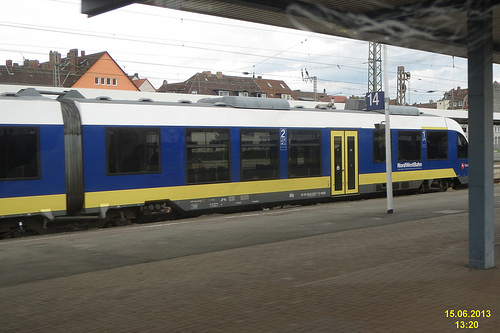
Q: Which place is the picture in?
A: It is at the train station.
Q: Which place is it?
A: It is a train station.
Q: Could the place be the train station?
A: Yes, it is the train station.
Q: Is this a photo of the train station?
A: Yes, it is showing the train station.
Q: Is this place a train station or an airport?
A: It is a train station.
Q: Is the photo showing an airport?
A: No, the picture is showing a train station.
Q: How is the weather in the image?
A: It is cloudy.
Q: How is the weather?
A: It is cloudy.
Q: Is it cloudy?
A: Yes, it is cloudy.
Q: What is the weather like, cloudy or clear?
A: It is cloudy.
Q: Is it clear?
A: No, it is cloudy.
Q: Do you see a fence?
A: No, there are no fences.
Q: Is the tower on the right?
A: Yes, the tower is on the right of the image.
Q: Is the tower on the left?
A: No, the tower is on the right of the image.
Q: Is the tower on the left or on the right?
A: The tower is on the right of the image.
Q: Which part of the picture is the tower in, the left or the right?
A: The tower is on the right of the image.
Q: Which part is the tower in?
A: The tower is on the right of the image.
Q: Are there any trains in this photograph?
A: Yes, there is a train.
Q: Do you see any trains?
A: Yes, there is a train.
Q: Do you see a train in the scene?
A: Yes, there is a train.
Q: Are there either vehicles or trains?
A: Yes, there is a train.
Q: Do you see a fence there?
A: No, there are no fences.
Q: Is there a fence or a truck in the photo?
A: No, there are no fences or trucks.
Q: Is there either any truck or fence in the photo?
A: No, there are no fences or trucks.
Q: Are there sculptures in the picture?
A: No, there are no sculptures.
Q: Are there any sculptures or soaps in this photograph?
A: No, there are no sculptures or soaps.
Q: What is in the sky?
A: The clouds are in the sky.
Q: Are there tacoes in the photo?
A: No, there are no tacoes.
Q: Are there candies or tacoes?
A: No, there are no tacoes or candies.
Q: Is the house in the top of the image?
A: Yes, the house is in the top of the image.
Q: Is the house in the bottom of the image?
A: No, the house is in the top of the image.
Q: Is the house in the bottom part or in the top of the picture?
A: The house is in the top of the image.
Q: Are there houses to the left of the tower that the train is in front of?
A: Yes, there is a house to the left of the tower.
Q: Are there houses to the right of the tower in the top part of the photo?
A: No, the house is to the left of the tower.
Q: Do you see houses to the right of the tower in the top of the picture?
A: No, the house is to the left of the tower.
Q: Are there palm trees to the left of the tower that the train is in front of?
A: No, there is a house to the left of the tower.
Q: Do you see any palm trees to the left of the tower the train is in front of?
A: No, there is a house to the left of the tower.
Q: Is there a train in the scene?
A: Yes, there is a train.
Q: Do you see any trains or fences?
A: Yes, there is a train.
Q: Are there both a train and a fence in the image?
A: No, there is a train but no fences.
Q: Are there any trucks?
A: No, there are no trucks.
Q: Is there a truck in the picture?
A: No, there are no trucks.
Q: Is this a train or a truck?
A: This is a train.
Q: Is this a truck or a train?
A: This is a train.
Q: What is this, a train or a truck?
A: This is a train.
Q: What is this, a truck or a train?
A: This is a train.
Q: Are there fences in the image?
A: No, there are no fences.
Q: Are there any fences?
A: No, there are no fences.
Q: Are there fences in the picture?
A: No, there are no fences.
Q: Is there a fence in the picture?
A: No, there are no fences.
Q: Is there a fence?
A: No, there are no fences.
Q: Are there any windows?
A: Yes, there are windows.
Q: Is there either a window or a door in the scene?
A: Yes, there are windows.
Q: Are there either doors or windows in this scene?
A: Yes, there are windows.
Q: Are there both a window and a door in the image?
A: Yes, there are both a window and a door.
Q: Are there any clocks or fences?
A: No, there are no fences or clocks.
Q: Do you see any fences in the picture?
A: No, there are no fences.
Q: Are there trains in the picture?
A: Yes, there is a train.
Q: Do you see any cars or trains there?
A: Yes, there is a train.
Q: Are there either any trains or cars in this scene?
A: Yes, there is a train.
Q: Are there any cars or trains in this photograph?
A: Yes, there is a train.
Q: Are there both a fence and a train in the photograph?
A: No, there is a train but no fences.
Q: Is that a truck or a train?
A: That is a train.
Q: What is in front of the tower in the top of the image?
A: The train is in front of the tower.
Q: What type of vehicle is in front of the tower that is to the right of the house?
A: The vehicle is a train.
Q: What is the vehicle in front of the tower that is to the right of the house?
A: The vehicle is a train.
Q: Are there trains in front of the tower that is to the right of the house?
A: Yes, there is a train in front of the tower.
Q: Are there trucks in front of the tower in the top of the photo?
A: No, there is a train in front of the tower.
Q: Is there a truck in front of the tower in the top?
A: No, there is a train in front of the tower.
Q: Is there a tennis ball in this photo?
A: No, there are no tennis balls.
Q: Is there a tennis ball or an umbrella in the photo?
A: No, there are no tennis balls or umbrellas.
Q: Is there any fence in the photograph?
A: No, there are no fences.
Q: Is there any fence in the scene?
A: No, there are no fences.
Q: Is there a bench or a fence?
A: No, there are no fences or benches.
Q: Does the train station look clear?
A: Yes, the train station is clear.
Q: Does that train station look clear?
A: Yes, the train station is clear.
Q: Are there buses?
A: Yes, there is a bus.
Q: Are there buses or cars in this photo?
A: Yes, there is a bus.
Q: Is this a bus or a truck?
A: This is a bus.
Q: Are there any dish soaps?
A: No, there are no dish soaps.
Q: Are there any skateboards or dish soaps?
A: No, there are no dish soaps or skateboards.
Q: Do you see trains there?
A: Yes, there is a train.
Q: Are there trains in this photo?
A: Yes, there is a train.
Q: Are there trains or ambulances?
A: Yes, there is a train.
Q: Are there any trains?
A: Yes, there is a train.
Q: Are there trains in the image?
A: Yes, there is a train.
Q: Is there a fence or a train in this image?
A: Yes, there is a train.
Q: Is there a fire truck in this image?
A: No, there are no fire trucks.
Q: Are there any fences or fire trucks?
A: No, there are no fire trucks or fences.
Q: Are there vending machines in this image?
A: No, there are no vending machines.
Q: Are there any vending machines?
A: No, there are no vending machines.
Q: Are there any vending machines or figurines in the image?
A: No, there are no vending machines or figurines.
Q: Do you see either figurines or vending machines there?
A: No, there are no vending machines or figurines.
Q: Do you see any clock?
A: No, there are no clocks.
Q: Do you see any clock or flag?
A: No, there are no clocks or flags.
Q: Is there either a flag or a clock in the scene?
A: No, there are no clocks or flags.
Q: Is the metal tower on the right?
A: Yes, the tower is on the right of the image.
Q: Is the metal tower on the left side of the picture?
A: No, the tower is on the right of the image.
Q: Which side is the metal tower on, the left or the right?
A: The tower is on the right of the image.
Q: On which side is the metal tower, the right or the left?
A: The tower is on the right of the image.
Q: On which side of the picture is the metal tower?
A: The tower is on the right of the image.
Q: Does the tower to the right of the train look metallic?
A: Yes, the tower is metallic.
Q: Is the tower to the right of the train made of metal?
A: Yes, the tower is made of metal.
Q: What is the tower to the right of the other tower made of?
A: The tower is made of metal.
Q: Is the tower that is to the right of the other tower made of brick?
A: No, the tower is made of metal.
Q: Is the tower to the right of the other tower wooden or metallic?
A: The tower is metallic.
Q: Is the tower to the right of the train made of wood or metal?
A: The tower is made of metal.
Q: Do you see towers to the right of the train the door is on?
A: Yes, there is a tower to the right of the train.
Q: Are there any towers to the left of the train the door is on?
A: No, the tower is to the right of the train.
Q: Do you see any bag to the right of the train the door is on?
A: No, there is a tower to the right of the train.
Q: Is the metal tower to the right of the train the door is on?
A: Yes, the tower is to the right of the train.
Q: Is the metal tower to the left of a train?
A: No, the tower is to the right of a train.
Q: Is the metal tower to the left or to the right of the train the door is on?
A: The tower is to the right of the train.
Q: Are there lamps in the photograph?
A: No, there are no lamps.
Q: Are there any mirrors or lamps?
A: No, there are no lamps or mirrors.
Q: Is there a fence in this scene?
A: No, there are no fences.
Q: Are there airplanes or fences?
A: No, there are no fences or airplanes.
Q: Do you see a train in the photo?
A: Yes, there is a train.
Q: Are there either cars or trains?
A: Yes, there is a train.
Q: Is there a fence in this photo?
A: No, there are no fences.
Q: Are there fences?
A: No, there are no fences.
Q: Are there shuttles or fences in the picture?
A: No, there are no fences or shuttles.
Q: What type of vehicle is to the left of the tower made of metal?
A: The vehicle is a train.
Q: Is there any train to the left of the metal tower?
A: Yes, there is a train to the left of the tower.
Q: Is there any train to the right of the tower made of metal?
A: No, the train is to the left of the tower.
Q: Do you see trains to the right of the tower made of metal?
A: No, the train is to the left of the tower.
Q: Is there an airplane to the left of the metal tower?
A: No, there is a train to the left of the tower.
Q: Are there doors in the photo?
A: Yes, there is a door.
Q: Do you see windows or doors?
A: Yes, there is a door.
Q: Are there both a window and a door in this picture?
A: Yes, there are both a door and a window.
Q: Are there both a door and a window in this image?
A: Yes, there are both a door and a window.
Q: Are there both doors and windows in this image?
A: Yes, there are both a door and a window.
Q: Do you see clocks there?
A: No, there are no clocks.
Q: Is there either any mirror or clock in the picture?
A: No, there are no clocks or mirrors.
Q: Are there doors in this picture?
A: Yes, there is a door.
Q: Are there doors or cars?
A: Yes, there is a door.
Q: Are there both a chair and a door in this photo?
A: No, there is a door but no chairs.